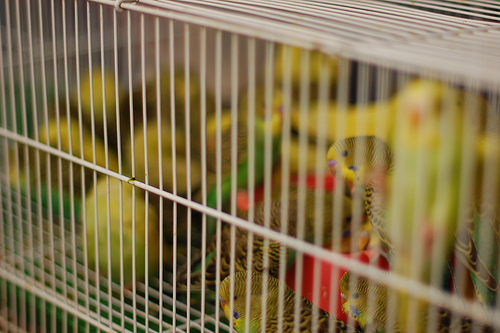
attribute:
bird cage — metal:
[107, 33, 452, 305]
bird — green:
[186, 112, 345, 264]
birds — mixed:
[60, 69, 440, 302]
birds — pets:
[29, 23, 435, 319]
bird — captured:
[321, 122, 433, 279]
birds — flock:
[159, 86, 454, 331]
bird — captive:
[315, 136, 438, 292]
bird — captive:
[211, 262, 340, 329]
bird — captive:
[330, 258, 424, 331]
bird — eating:
[315, 189, 381, 254]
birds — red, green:
[82, 60, 462, 312]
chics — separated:
[203, 132, 493, 328]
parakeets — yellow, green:
[200, 141, 278, 229]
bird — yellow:
[324, 135, 499, 292]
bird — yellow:
[338, 262, 453, 330]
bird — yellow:
[215, 270, 357, 331]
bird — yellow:
[213, 190, 370, 276]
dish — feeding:
[262, 173, 402, 314]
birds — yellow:
[59, 34, 481, 319]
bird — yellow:
[290, 100, 394, 199]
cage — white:
[1, 2, 499, 331]